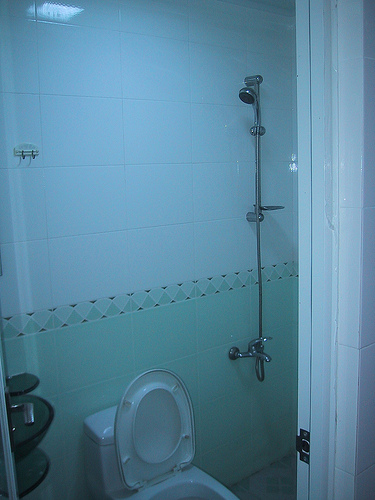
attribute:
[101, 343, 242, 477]
toilet seat — up, white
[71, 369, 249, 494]
toilet — white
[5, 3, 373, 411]
wall — white, tiles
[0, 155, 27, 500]
door — metal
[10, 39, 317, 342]
tile — decorative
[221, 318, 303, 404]
faucet — metal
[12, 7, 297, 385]
tiles — square, white, large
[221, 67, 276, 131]
shower head — metal, plastic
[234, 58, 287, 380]
pipe — metallic, long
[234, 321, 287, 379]
tap — metallic, shiny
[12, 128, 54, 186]
hanger — metal, plastic